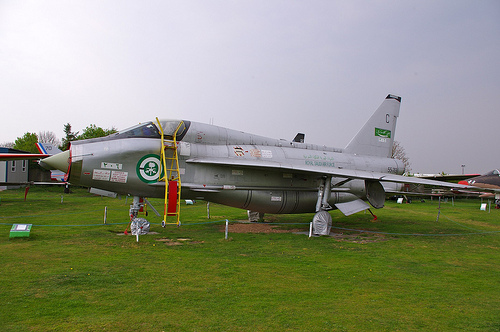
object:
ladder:
[159, 132, 188, 229]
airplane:
[36, 94, 481, 237]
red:
[450, 178, 470, 186]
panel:
[165, 177, 182, 217]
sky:
[0, 0, 500, 174]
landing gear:
[312, 208, 336, 237]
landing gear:
[244, 208, 267, 224]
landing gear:
[128, 194, 151, 237]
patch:
[135, 155, 162, 182]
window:
[20, 158, 27, 166]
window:
[10, 166, 15, 171]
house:
[1, 146, 57, 191]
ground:
[0, 184, 500, 331]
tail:
[345, 93, 407, 157]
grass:
[0, 188, 500, 330]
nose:
[39, 145, 75, 174]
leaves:
[14, 139, 26, 146]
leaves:
[93, 130, 102, 136]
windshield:
[148, 114, 184, 136]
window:
[112, 122, 160, 140]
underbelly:
[194, 184, 355, 215]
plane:
[444, 168, 500, 210]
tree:
[9, 132, 40, 161]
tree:
[57, 122, 79, 151]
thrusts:
[381, 155, 406, 178]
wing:
[183, 157, 483, 192]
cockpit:
[124, 116, 192, 144]